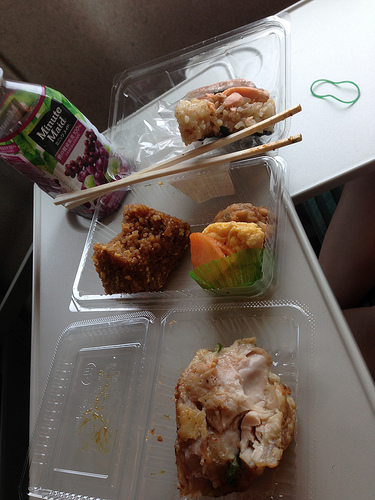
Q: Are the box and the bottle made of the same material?
A: Yes, both the box and the bottle are made of plastic.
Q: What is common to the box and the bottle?
A: The material, both the box and the bottle are plastic.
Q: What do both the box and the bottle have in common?
A: The material, both the box and the bottle are plastic.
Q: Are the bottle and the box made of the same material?
A: Yes, both the bottle and the box are made of plastic.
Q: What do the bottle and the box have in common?
A: The material, both the bottle and the box are plastic.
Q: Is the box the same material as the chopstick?
A: No, the box is made of plastic and the chopstick is made of wood.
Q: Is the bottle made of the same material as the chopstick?
A: No, the bottle is made of plastic and the chopstick is made of wood.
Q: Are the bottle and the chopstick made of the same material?
A: No, the bottle is made of plastic and the chopstick is made of wood.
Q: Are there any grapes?
A: Yes, there are grapes.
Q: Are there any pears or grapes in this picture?
A: Yes, there are grapes.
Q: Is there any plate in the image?
A: No, there are no plates.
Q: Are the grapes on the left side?
A: Yes, the grapes are on the left of the image.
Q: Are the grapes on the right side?
A: No, the grapes are on the left of the image.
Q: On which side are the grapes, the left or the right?
A: The grapes are on the left of the image.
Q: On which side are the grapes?
A: The grapes are on the left of the image.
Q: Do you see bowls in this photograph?
A: No, there are no bowls.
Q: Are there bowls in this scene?
A: No, there are no bowls.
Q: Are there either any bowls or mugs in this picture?
A: No, there are no bowls or mugs.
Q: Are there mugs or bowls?
A: No, there are no bowls or mugs.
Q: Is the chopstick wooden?
A: Yes, the chopstick is wooden.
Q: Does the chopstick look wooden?
A: Yes, the chopstick is wooden.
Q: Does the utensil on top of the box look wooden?
A: Yes, the chopstick is wooden.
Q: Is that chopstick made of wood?
A: Yes, the chopstick is made of wood.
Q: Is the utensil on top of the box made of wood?
A: Yes, the chopstick is made of wood.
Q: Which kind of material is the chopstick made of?
A: The chopstick is made of wood.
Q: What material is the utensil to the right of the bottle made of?
A: The chopstick is made of wood.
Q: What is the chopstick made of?
A: The chopstick is made of wood.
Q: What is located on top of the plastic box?
A: The chop stick is on top of the box.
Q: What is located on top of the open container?
A: The chop stick is on top of the box.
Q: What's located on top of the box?
A: The chop stick is on top of the box.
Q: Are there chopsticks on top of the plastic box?
A: Yes, there is a chopstick on top of the box.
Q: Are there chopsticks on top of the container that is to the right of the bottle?
A: Yes, there is a chopstick on top of the box.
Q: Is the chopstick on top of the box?
A: Yes, the chopstick is on top of the box.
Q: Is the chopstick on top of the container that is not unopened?
A: Yes, the chopstick is on top of the box.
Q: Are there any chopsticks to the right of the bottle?
A: Yes, there is a chopstick to the right of the bottle.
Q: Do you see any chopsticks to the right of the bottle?
A: Yes, there is a chopstick to the right of the bottle.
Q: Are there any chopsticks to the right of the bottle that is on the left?
A: Yes, there is a chopstick to the right of the bottle.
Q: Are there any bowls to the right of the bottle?
A: No, there is a chopstick to the right of the bottle.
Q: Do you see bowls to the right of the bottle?
A: No, there is a chopstick to the right of the bottle.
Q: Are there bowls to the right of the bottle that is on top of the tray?
A: No, there is a chopstick to the right of the bottle.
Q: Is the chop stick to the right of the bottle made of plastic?
A: Yes, the chop stick is to the right of the bottle.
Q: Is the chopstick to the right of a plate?
A: No, the chopstick is to the right of the bottle.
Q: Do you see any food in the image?
A: Yes, there is food.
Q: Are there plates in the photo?
A: No, there are no plates.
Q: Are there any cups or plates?
A: No, there are no plates or cups.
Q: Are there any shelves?
A: No, there are no shelves.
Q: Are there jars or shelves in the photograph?
A: No, there are no shelves or jars.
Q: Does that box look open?
A: Yes, the box is open.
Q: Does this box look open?
A: Yes, the box is open.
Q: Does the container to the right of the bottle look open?
A: Yes, the box is open.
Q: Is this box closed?
A: No, the box is open.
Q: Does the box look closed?
A: No, the box is open.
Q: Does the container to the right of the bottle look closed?
A: No, the box is open.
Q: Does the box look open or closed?
A: The box is open.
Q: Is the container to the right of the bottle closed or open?
A: The box is open.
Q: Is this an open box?
A: Yes, this is an open box.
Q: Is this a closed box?
A: No, this is an open box.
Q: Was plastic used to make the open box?
A: Yes, the box is made of plastic.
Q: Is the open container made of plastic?
A: Yes, the box is made of plastic.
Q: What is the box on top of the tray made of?
A: The box is made of plastic.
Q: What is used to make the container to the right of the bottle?
A: The box is made of plastic.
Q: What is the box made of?
A: The box is made of plastic.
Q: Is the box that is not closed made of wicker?
A: No, the box is made of plastic.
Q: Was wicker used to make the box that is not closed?
A: No, the box is made of plastic.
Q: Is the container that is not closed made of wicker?
A: No, the box is made of plastic.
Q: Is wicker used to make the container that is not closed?
A: No, the box is made of plastic.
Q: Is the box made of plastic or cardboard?
A: The box is made of plastic.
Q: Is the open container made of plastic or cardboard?
A: The box is made of plastic.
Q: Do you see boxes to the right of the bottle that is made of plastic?
A: Yes, there is a box to the right of the bottle.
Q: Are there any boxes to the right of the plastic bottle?
A: Yes, there is a box to the right of the bottle.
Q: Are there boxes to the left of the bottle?
A: No, the box is to the right of the bottle.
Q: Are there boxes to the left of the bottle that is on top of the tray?
A: No, the box is to the right of the bottle.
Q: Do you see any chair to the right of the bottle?
A: No, there is a box to the right of the bottle.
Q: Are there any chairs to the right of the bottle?
A: No, there is a box to the right of the bottle.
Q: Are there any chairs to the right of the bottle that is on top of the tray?
A: No, there is a box to the right of the bottle.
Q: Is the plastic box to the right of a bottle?
A: Yes, the box is to the right of a bottle.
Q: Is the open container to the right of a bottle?
A: Yes, the box is to the right of a bottle.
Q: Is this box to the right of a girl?
A: No, the box is to the right of a bottle.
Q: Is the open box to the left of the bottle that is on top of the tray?
A: No, the box is to the right of the bottle.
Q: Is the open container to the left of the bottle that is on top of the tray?
A: No, the box is to the right of the bottle.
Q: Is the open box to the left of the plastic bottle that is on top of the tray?
A: No, the box is to the right of the bottle.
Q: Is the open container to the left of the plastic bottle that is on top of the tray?
A: No, the box is to the right of the bottle.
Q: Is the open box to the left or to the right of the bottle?
A: The box is to the right of the bottle.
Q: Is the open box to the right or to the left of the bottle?
A: The box is to the right of the bottle.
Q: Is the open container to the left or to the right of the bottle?
A: The box is to the right of the bottle.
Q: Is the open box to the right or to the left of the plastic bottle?
A: The box is to the right of the bottle.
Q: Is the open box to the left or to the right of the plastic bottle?
A: The box is to the right of the bottle.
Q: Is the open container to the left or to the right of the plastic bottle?
A: The box is to the right of the bottle.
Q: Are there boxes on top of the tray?
A: Yes, there is a box on top of the tray.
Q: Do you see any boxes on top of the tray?
A: Yes, there is a box on top of the tray.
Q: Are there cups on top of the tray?
A: No, there is a box on top of the tray.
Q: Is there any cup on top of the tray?
A: No, there is a box on top of the tray.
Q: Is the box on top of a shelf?
A: No, the box is on top of the tray.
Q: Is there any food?
A: Yes, there is food.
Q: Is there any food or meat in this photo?
A: Yes, there is food.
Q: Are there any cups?
A: No, there are no cups.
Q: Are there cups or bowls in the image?
A: No, there are no cups or bowls.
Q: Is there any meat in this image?
A: Yes, there is meat.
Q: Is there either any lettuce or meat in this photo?
A: Yes, there is meat.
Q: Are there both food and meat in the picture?
A: Yes, there are both meat and food.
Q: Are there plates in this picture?
A: No, there are no plates.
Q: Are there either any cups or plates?
A: No, there are no plates or cups.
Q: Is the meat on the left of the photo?
A: Yes, the meat is on the left of the image.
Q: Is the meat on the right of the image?
A: No, the meat is on the left of the image.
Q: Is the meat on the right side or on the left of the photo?
A: The meat is on the left of the image.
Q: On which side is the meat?
A: The meat is on the left of the image.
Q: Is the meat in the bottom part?
A: Yes, the meat is in the bottom of the image.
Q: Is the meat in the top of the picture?
A: No, the meat is in the bottom of the image.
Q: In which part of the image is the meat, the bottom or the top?
A: The meat is in the bottom of the image.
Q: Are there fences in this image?
A: No, there are no fences.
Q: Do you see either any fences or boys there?
A: No, there are no fences or boys.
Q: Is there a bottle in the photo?
A: Yes, there is a bottle.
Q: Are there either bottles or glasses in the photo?
A: Yes, there is a bottle.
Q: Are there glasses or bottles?
A: Yes, there is a bottle.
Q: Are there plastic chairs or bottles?
A: Yes, there is a plastic bottle.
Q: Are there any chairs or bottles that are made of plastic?
A: Yes, the bottle is made of plastic.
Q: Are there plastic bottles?
A: Yes, there is a bottle that is made of plastic.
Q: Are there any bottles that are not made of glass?
A: Yes, there is a bottle that is made of plastic.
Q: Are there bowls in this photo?
A: No, there are no bowls.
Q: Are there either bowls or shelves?
A: No, there are no bowls or shelves.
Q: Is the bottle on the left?
A: Yes, the bottle is on the left of the image.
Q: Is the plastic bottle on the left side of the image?
A: Yes, the bottle is on the left of the image.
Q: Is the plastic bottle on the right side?
A: No, the bottle is on the left of the image.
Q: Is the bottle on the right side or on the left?
A: The bottle is on the left of the image.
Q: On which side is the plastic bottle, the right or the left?
A: The bottle is on the left of the image.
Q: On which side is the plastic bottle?
A: The bottle is on the left of the image.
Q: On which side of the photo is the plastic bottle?
A: The bottle is on the left of the image.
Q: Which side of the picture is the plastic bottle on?
A: The bottle is on the left of the image.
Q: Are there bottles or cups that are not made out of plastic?
A: No, there is a bottle but it is made of plastic.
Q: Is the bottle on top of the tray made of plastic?
A: Yes, the bottle is made of plastic.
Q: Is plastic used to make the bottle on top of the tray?
A: Yes, the bottle is made of plastic.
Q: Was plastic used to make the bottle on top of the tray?
A: Yes, the bottle is made of plastic.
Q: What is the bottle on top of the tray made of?
A: The bottle is made of plastic.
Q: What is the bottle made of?
A: The bottle is made of plastic.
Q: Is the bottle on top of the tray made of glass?
A: No, the bottle is made of plastic.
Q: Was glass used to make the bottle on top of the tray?
A: No, the bottle is made of plastic.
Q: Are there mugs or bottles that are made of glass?
A: No, there is a bottle but it is made of plastic.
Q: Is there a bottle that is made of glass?
A: No, there is a bottle but it is made of plastic.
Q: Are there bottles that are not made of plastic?
A: No, there is a bottle but it is made of plastic.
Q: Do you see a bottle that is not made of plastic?
A: No, there is a bottle but it is made of plastic.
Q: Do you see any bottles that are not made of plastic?
A: No, there is a bottle but it is made of plastic.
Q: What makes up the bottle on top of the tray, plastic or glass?
A: The bottle is made of plastic.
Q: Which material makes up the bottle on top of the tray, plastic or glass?
A: The bottle is made of plastic.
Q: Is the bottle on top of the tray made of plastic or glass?
A: The bottle is made of plastic.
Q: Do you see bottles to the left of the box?
A: Yes, there is a bottle to the left of the box.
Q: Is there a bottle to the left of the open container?
A: Yes, there is a bottle to the left of the box.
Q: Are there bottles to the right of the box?
A: No, the bottle is to the left of the box.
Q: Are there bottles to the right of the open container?
A: No, the bottle is to the left of the box.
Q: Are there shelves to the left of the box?
A: No, there is a bottle to the left of the box.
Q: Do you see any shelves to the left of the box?
A: No, there is a bottle to the left of the box.